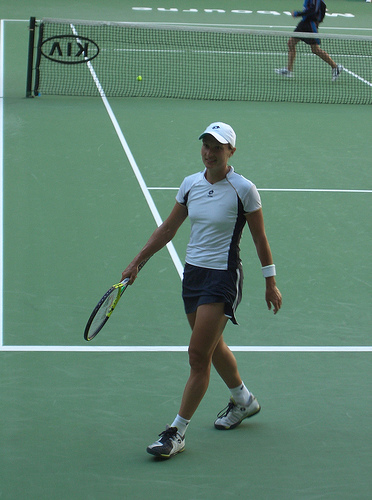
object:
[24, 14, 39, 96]
pole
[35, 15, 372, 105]
net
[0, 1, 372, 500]
floor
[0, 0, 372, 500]
court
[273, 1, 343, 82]
tennis player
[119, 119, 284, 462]
tennis player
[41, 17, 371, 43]
border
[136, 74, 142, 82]
ball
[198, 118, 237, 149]
cap